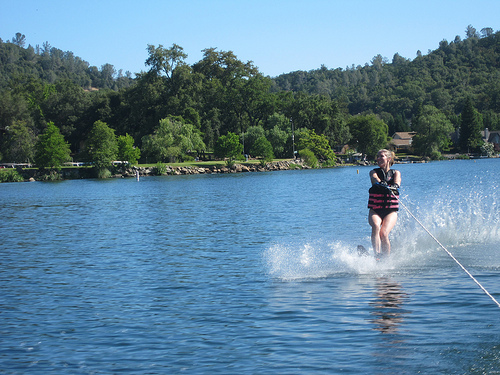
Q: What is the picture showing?
A: It is showing a lake.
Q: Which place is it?
A: It is a lake.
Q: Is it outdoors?
A: Yes, it is outdoors.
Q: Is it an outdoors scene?
A: Yes, it is outdoors.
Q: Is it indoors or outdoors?
A: It is outdoors.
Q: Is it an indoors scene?
A: No, it is outdoors.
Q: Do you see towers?
A: No, there are no towers.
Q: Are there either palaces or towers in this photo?
A: No, there are no towers or palaces.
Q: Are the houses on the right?
A: Yes, the houses are on the right of the image.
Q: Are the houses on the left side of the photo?
A: No, the houses are on the right of the image.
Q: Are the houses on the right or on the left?
A: The houses are on the right of the image.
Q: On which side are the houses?
A: The houses are on the right of the image.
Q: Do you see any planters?
A: No, there are no planters.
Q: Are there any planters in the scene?
A: No, there are no planters.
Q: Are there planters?
A: No, there are no planters.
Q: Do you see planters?
A: No, there are no planters.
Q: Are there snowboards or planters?
A: No, there are no planters or snowboards.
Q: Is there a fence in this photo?
A: No, there are no fences.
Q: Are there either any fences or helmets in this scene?
A: No, there are no fences or helmets.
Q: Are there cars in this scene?
A: No, there are no cars.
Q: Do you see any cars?
A: No, there are no cars.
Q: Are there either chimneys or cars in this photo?
A: No, there are no cars or chimneys.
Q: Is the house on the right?
A: Yes, the house is on the right of the image.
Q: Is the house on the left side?
A: No, the house is on the right of the image.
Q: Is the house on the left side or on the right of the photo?
A: The house is on the right of the image.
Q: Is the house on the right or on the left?
A: The house is on the right of the image.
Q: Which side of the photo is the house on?
A: The house is on the right of the image.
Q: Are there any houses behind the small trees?
A: Yes, there is a house behind the trees.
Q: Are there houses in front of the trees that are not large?
A: No, the house is behind the trees.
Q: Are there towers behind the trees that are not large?
A: No, there is a house behind the trees.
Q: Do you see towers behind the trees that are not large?
A: No, there is a house behind the trees.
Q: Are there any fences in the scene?
A: No, there are no fences.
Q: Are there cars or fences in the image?
A: No, there are no fences or cars.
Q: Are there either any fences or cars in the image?
A: No, there are no fences or cars.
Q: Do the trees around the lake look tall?
A: Yes, the trees are tall.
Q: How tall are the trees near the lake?
A: The trees are tall.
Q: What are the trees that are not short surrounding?
A: The trees are surrounding the houses.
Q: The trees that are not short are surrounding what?
A: The trees are surrounding the houses.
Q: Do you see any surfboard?
A: No, there are no surfboards.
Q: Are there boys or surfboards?
A: No, there are no surfboards or boys.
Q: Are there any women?
A: Yes, there is a woman.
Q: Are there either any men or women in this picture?
A: Yes, there is a woman.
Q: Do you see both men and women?
A: No, there is a woman but no men.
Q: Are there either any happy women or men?
A: Yes, there is a happy woman.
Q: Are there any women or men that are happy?
A: Yes, the woman is happy.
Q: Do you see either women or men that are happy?
A: Yes, the woman is happy.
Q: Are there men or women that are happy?
A: Yes, the woman is happy.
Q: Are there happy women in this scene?
A: Yes, there is a happy woman.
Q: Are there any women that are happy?
A: Yes, there is a woman that is happy.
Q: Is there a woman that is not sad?
A: Yes, there is a happy woman.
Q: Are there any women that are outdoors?
A: Yes, there is a woman that is outdoors.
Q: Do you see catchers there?
A: No, there are no catchers.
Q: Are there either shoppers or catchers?
A: No, there are no catchers or shoppers.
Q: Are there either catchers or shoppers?
A: No, there are no catchers or shoppers.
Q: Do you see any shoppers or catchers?
A: No, there are no catchers or shoppers.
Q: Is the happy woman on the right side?
A: Yes, the woman is on the right of the image.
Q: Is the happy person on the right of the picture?
A: Yes, the woman is on the right of the image.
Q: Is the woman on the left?
A: No, the woman is on the right of the image.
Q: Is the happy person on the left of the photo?
A: No, the woman is on the right of the image.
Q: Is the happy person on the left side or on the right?
A: The woman is on the right of the image.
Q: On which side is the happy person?
A: The woman is on the right of the image.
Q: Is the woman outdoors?
A: Yes, the woman is outdoors.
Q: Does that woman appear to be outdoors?
A: Yes, the woman is outdoors.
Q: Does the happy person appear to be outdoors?
A: Yes, the woman is outdoors.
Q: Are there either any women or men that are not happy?
A: No, there is a woman but she is happy.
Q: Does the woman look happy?
A: Yes, the woman is happy.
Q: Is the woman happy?
A: Yes, the woman is happy.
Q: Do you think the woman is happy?
A: Yes, the woman is happy.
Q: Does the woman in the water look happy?
A: Yes, the woman is happy.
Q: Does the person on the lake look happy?
A: Yes, the woman is happy.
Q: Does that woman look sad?
A: No, the woman is happy.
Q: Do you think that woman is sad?
A: No, the woman is happy.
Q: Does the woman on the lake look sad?
A: No, the woman is happy.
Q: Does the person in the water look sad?
A: No, the woman is happy.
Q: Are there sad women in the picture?
A: No, there is a woman but she is happy.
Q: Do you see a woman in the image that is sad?
A: No, there is a woman but she is happy.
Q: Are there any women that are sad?
A: No, there is a woman but she is happy.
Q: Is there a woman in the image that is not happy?
A: No, there is a woman but she is happy.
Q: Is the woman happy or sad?
A: The woman is happy.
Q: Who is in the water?
A: The woman is in the water.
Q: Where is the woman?
A: The woman is in the water.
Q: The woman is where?
A: The woman is on the lake.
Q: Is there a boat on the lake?
A: No, there is a woman on the lake.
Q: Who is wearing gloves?
A: The woman is wearing gloves.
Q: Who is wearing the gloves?
A: The woman is wearing gloves.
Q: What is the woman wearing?
A: The woman is wearing gloves.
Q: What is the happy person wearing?
A: The woman is wearing gloves.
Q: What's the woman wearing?
A: The woman is wearing gloves.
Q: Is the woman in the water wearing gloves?
A: Yes, the woman is wearing gloves.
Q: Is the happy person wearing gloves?
A: Yes, the woman is wearing gloves.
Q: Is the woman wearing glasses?
A: No, the woman is wearing gloves.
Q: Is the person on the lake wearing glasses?
A: No, the woman is wearing gloves.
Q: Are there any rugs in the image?
A: No, there are no rugs.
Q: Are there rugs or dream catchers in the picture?
A: No, there are no rugs or dream catchers.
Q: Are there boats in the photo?
A: No, there are no boats.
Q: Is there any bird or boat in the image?
A: No, there are no boats or birds.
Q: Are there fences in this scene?
A: No, there are no fences.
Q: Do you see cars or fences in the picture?
A: No, there are no fences or cars.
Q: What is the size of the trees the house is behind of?
A: The trees are small.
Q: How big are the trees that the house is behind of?
A: The trees are small.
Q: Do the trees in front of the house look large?
A: No, the trees are small.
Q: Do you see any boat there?
A: No, there are no boats.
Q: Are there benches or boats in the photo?
A: No, there are no boats or benches.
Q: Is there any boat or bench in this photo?
A: No, there are no boats or benches.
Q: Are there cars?
A: No, there are no cars.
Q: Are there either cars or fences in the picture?
A: No, there are no cars or fences.